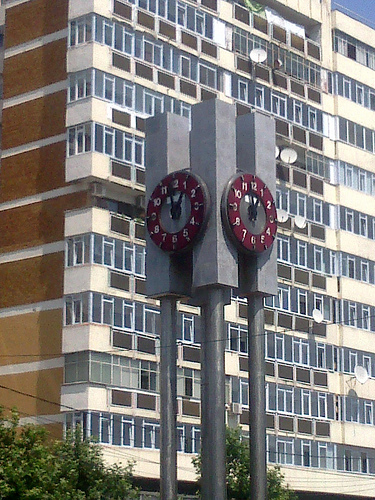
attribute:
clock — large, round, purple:
[227, 174, 280, 250]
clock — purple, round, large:
[146, 171, 207, 248]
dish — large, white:
[346, 357, 370, 385]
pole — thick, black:
[150, 294, 179, 498]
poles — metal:
[153, 289, 269, 374]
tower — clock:
[131, 86, 294, 497]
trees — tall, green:
[0, 404, 299, 498]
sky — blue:
[332, 2, 372, 25]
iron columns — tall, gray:
[149, 279, 283, 498]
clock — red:
[223, 168, 286, 259]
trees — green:
[2, 412, 136, 497]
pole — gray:
[244, 304, 284, 498]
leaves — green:
[51, 442, 102, 467]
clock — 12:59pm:
[207, 173, 345, 301]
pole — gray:
[158, 295, 178, 499]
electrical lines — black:
[0, 313, 372, 483]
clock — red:
[139, 166, 208, 254]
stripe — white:
[10, 354, 63, 375]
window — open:
[63, 293, 84, 326]